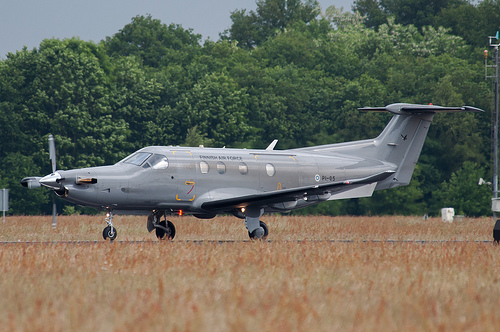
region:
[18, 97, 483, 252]
The plane on the runway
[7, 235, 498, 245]
The runway below the plane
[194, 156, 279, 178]
The windows on the side of the plane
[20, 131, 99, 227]
The plane's propeller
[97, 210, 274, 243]
The plane's landing gear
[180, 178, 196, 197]
The number 7 on the plane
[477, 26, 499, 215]
The tower behind the plane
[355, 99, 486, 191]
The tail of the plane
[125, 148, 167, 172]
The windshield of the plane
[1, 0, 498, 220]
The trees in the background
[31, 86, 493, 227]
the airplane that is about to take off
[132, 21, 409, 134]
trees in the back ground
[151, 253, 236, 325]
the burned grass in the fore ground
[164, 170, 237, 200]
number 7 on the airplane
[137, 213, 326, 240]
the landing gear of the airplane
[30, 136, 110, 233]
the propellers of the airplane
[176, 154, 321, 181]
four windows of the airplane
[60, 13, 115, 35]
the cloudy skies in the back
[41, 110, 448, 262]
the grey airplane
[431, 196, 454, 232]
a white bucket in the back ground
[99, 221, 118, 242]
Front wheel on a jet.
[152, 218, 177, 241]
Larger side wheel on a gray jet.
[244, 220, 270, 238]
Back wheel on a gray jet.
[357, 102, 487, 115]
Thin panel of wing on the tail end of a plane.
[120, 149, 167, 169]
Front windshield on the gray plane.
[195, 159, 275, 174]
Four round side windows on a jet.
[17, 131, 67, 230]
Gray propeller on the front of a gray plane.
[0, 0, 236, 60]
Dark blue and gray sky above the trees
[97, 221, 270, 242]
All the wheels of a gray jet.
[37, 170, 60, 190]
Pointy silver nose of a plane.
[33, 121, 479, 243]
the grey airplane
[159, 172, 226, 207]
the number 7 on the airplane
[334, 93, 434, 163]
the wing of the back of the plane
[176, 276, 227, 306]
the burnt grass on the foreground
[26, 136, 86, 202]
the propellers on front of the plane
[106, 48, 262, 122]
the bushes and trees behind the plane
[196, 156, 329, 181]
the four windows on the side of the plane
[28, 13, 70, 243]
the nice scene of the plane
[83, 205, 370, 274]
the landing gear for the plane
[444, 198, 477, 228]
a white bucket in the far background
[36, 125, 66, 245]
The propeller on a plane.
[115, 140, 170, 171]
The windshield on an airplane.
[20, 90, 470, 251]
The airplane is gray.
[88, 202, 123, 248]
The front wheel on the airplane.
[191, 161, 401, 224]
The wing on the airplane.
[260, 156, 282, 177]
A passenger window on the airplane.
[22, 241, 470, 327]
Brown grass near the airplane.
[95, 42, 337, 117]
Green trees behind the airplane.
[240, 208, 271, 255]
A wheel on an airplane.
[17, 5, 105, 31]
The sky is gray.